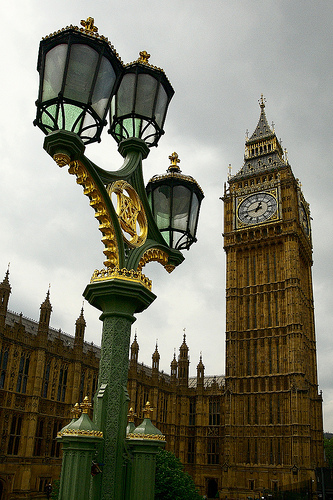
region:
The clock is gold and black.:
[216, 185, 287, 227]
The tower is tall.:
[222, 194, 319, 496]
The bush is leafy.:
[156, 448, 183, 497]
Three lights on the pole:
[60, 95, 225, 252]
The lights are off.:
[46, 42, 215, 243]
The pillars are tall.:
[129, 331, 232, 387]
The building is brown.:
[222, 232, 328, 498]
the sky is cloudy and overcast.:
[165, 280, 231, 354]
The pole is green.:
[57, 296, 164, 483]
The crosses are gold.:
[131, 405, 166, 499]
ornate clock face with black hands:
[236, 191, 277, 224]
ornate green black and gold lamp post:
[32, 16, 204, 497]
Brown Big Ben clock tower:
[219, 93, 326, 498]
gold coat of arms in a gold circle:
[105, 179, 147, 247]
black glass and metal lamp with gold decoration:
[33, 17, 125, 145]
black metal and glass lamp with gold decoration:
[108, 50, 174, 147]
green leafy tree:
[155, 446, 202, 498]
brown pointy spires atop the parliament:
[0, 262, 225, 498]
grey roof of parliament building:
[0, 307, 221, 498]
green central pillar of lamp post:
[82, 269, 157, 499]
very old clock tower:
[211, 137, 327, 445]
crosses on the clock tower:
[220, 94, 300, 183]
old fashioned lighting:
[24, 10, 225, 314]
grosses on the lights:
[30, 9, 209, 199]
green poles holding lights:
[39, 280, 176, 479]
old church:
[0, 125, 332, 431]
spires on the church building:
[0, 257, 237, 407]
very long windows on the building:
[1, 331, 49, 456]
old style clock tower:
[221, 252, 330, 481]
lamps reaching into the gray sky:
[18, 23, 219, 295]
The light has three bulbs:
[36, 11, 259, 259]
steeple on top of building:
[223, 92, 308, 216]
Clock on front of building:
[236, 187, 278, 230]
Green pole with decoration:
[88, 304, 139, 496]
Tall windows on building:
[226, 372, 304, 496]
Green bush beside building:
[141, 443, 207, 490]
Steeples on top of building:
[146, 332, 219, 376]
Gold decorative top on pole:
[141, 399, 157, 421]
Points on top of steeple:
[242, 127, 247, 141]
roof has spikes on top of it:
[3, 303, 103, 369]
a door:
[194, 469, 221, 493]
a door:
[201, 475, 220, 498]